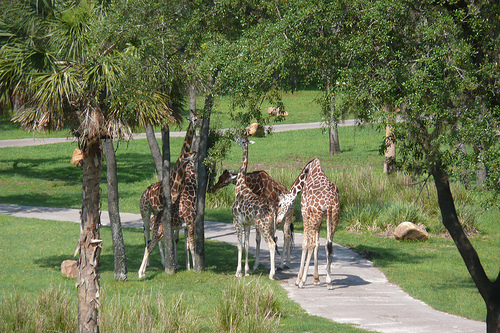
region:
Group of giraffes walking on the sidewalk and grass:
[137, 109, 335, 286]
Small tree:
[0, 1, 185, 330]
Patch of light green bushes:
[8, 283, 283, 330]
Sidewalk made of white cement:
[0, 113, 455, 147]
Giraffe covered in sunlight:
[276, 160, 346, 290]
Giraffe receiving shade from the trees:
[134, 110, 206, 276]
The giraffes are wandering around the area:
[140, 108, 350, 289]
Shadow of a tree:
[0, 144, 160, 186]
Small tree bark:
[395, 222, 431, 244]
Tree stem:
[76, 139, 107, 331]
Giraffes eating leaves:
[159, 91, 356, 302]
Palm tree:
[39, 19, 154, 181]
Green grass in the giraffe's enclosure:
[172, 238, 308, 314]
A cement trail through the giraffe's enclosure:
[214, 207, 422, 331]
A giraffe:
[230, 100, 317, 261]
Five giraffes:
[127, 110, 364, 323]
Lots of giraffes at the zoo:
[102, 77, 380, 332]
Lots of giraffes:
[121, 109, 298, 271]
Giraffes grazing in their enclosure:
[16, 122, 368, 299]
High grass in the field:
[341, 169, 415, 248]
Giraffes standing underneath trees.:
[135, 111, 339, 288]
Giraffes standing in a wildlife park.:
[16, 12, 483, 331]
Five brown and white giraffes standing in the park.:
[19, 32, 474, 304]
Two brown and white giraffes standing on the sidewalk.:
[212, 146, 342, 288]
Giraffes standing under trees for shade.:
[7, 3, 494, 328]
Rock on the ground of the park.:
[392, 215, 429, 245]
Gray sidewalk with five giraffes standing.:
[7, 170, 427, 323]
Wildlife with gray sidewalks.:
[7, 17, 492, 317]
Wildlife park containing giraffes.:
[12, 6, 487, 326]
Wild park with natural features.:
[25, 10, 485, 317]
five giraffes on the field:
[128, 93, 393, 278]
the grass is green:
[10, 221, 52, 267]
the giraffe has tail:
[294, 190, 368, 290]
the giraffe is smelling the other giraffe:
[239, 155, 369, 286]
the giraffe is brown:
[274, 157, 349, 252]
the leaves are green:
[132, 30, 266, 87]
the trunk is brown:
[42, 139, 147, 325]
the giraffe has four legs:
[271, 215, 373, 297]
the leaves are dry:
[77, 99, 132, 150]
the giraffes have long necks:
[165, 104, 221, 214]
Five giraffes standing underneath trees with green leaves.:
[134, 107, 342, 293]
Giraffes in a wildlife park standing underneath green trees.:
[0, 3, 496, 331]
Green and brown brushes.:
[3, 280, 286, 330]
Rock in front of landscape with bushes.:
[352, 168, 490, 244]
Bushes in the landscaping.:
[206, 160, 475, 237]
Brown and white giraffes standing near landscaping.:
[21, 7, 476, 306]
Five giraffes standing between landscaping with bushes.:
[135, 106, 342, 292]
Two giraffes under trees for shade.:
[139, 110, 209, 277]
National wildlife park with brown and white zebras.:
[30, 31, 454, 301]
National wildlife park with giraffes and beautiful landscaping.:
[15, 7, 490, 329]